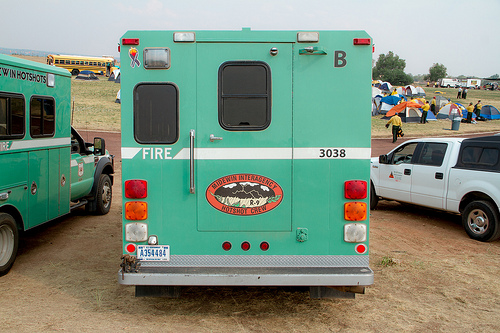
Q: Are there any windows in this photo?
A: Yes, there is a window.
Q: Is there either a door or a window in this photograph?
A: Yes, there is a window.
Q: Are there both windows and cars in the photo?
A: Yes, there are both a window and a car.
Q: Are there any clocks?
A: No, there are no clocks.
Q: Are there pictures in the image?
A: No, there are no pictures.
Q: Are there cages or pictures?
A: No, there are no pictures or cages.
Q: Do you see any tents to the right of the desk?
A: Yes, there is a tent to the right of the desk.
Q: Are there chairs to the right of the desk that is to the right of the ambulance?
A: No, there is a tent to the right of the desk.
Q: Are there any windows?
A: Yes, there is a window.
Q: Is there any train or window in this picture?
A: Yes, there is a window.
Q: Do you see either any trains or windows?
A: Yes, there is a window.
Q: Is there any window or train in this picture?
A: Yes, there is a window.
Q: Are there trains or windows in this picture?
A: Yes, there is a window.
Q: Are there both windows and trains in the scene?
A: No, there is a window but no trains.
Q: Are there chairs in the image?
A: No, there are no chairs.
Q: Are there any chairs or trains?
A: No, there are no chairs or trains.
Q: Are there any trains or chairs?
A: No, there are no chairs or trains.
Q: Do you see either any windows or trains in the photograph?
A: Yes, there is a window.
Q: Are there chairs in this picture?
A: No, there are no chairs.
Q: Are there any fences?
A: No, there are no fences.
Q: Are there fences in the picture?
A: No, there are no fences.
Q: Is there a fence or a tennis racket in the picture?
A: No, there are no fences or rackets.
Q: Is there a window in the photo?
A: Yes, there is a window.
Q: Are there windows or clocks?
A: Yes, there is a window.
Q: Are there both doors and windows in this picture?
A: Yes, there are both a window and a door.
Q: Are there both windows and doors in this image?
A: Yes, there are both a window and a door.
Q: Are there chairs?
A: No, there are no chairs.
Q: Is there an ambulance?
A: Yes, there is an ambulance.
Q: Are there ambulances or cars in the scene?
A: Yes, there is an ambulance.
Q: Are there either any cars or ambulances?
A: Yes, there is an ambulance.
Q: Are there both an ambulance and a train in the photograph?
A: No, there is an ambulance but no trains.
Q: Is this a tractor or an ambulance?
A: This is an ambulance.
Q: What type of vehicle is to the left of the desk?
A: The vehicle is an ambulance.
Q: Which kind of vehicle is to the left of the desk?
A: The vehicle is an ambulance.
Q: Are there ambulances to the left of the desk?
A: Yes, there is an ambulance to the left of the desk.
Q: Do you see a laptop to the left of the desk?
A: No, there is an ambulance to the left of the desk.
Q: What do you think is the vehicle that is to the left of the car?
A: The vehicle is an ambulance.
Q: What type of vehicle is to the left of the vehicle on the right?
A: The vehicle is an ambulance.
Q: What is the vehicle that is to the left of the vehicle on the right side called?
A: The vehicle is an ambulance.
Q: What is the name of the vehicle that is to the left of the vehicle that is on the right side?
A: The vehicle is an ambulance.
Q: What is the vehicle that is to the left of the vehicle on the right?
A: The vehicle is an ambulance.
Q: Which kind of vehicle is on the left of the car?
A: The vehicle is an ambulance.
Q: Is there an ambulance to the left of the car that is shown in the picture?
A: Yes, there is an ambulance to the left of the car.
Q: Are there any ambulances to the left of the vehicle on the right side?
A: Yes, there is an ambulance to the left of the car.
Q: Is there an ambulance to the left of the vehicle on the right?
A: Yes, there is an ambulance to the left of the car.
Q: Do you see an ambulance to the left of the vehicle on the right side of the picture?
A: Yes, there is an ambulance to the left of the car.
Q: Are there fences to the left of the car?
A: No, there is an ambulance to the left of the car.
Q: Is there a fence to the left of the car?
A: No, there is an ambulance to the left of the car.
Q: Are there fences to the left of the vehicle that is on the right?
A: No, there is an ambulance to the left of the car.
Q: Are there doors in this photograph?
A: Yes, there is a door.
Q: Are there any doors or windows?
A: Yes, there is a door.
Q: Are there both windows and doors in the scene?
A: Yes, there are both a door and a window.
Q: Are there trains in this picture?
A: No, there are no trains.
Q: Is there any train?
A: No, there are no trains.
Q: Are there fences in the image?
A: No, there are no fences.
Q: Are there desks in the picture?
A: Yes, there is a desk.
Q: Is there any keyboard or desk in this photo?
A: Yes, there is a desk.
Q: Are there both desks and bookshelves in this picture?
A: No, there is a desk but no bookshelves.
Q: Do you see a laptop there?
A: No, there are no laptops.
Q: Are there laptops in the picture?
A: No, there are no laptops.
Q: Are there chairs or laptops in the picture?
A: No, there are no laptops or chairs.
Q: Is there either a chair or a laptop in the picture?
A: No, there are no laptops or chairs.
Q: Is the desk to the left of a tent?
A: Yes, the desk is to the left of a tent.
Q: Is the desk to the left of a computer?
A: No, the desk is to the left of a tent.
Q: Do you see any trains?
A: No, there are no trains.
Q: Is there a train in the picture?
A: No, there are no trains.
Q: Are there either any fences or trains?
A: No, there are no trains or fences.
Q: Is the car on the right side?
A: Yes, the car is on the right of the image.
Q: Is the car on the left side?
A: No, the car is on the right of the image.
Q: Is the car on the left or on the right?
A: The car is on the right of the image.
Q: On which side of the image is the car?
A: The car is on the right of the image.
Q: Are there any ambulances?
A: Yes, there is an ambulance.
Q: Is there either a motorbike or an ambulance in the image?
A: Yes, there is an ambulance.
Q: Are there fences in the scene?
A: No, there are no fences.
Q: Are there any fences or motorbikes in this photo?
A: No, there are no fences or motorbikes.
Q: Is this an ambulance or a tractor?
A: This is an ambulance.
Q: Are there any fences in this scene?
A: No, there are no fences.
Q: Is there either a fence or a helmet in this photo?
A: No, there are no fences or helmets.